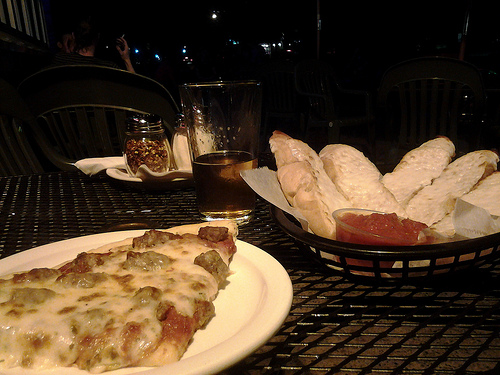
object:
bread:
[317, 141, 412, 218]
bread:
[382, 132, 455, 208]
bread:
[406, 149, 498, 226]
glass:
[183, 81, 268, 228]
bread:
[428, 172, 498, 243]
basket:
[272, 206, 500, 282]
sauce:
[333, 212, 429, 272]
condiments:
[126, 114, 174, 176]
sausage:
[192, 246, 227, 281]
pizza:
[0, 216, 240, 374]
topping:
[56, 269, 108, 289]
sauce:
[0, 240, 229, 371]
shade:
[416, 270, 499, 296]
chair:
[282, 70, 392, 164]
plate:
[0, 229, 295, 373]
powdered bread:
[269, 130, 356, 239]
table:
[0, 148, 500, 374]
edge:
[179, 240, 294, 374]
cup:
[328, 208, 427, 275]